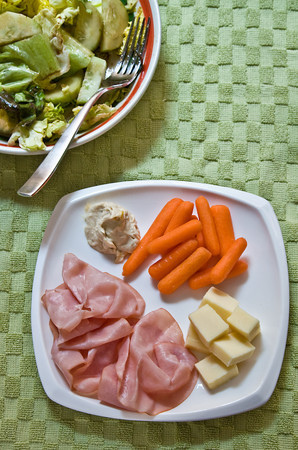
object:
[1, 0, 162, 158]
bowl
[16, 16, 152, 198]
fork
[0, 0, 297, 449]
cloth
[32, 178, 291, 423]
plate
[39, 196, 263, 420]
food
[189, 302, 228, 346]
cheese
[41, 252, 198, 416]
ham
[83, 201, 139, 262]
dip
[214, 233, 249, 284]
carrots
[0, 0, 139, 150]
lettuce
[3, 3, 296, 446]
table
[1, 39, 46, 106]
cucumber